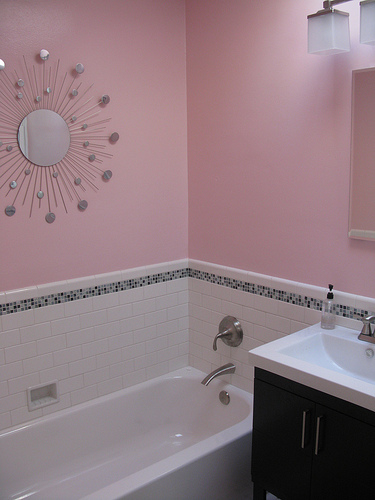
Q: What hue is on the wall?
A: A pink wall.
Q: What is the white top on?
A: A cabinet.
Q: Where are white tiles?
A: On the walls.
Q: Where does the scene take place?
A: In a bathroom.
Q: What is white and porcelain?
A: Bathtub.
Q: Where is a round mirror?
A: On the wall.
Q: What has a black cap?
A: Soap bottle.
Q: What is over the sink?
A: Faucet.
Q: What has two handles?
A: Cabinets.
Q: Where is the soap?
A: In a bottle.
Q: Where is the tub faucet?
A: Attached to white tiles.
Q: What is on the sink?
A: A bottle of soap.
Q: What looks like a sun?
A: The art on the wall.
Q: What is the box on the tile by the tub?
A: A soap holder.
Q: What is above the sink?
A: A mirror.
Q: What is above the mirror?
A: Light fixtures.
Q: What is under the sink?
A: A cabinet.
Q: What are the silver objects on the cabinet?
A: The door handles.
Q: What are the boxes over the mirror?
A: Lights.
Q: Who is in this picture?
A: No one.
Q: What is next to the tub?
A: A vanity.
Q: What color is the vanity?
A: Black.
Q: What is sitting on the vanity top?
A: Bottle of hand soap.